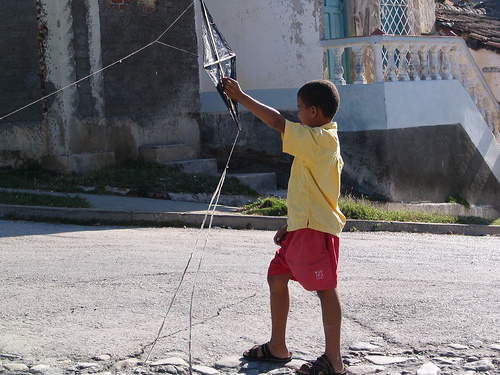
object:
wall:
[193, 0, 318, 116]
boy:
[218, 75, 346, 375]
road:
[0, 211, 499, 373]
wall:
[4, 1, 212, 171]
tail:
[137, 126, 244, 375]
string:
[142, 123, 239, 373]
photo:
[0, 0, 497, 375]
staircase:
[313, 38, 500, 183]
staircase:
[137, 132, 287, 200]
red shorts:
[263, 226, 342, 292]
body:
[219, 77, 346, 375]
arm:
[237, 90, 313, 148]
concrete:
[0, 219, 500, 375]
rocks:
[356, 342, 416, 373]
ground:
[0, 211, 500, 375]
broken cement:
[1, 339, 499, 374]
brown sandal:
[296, 352, 348, 375]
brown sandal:
[243, 342, 295, 362]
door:
[313, 0, 354, 88]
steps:
[163, 156, 219, 174]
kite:
[189, 0, 244, 130]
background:
[0, 0, 500, 231]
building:
[198, 0, 500, 202]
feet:
[242, 341, 290, 360]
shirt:
[277, 120, 349, 238]